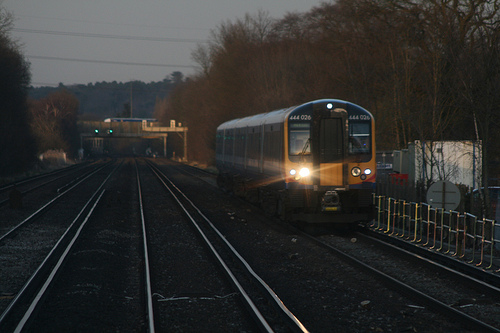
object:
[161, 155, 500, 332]
railroad tracks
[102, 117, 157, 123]
vehicle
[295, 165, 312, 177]
light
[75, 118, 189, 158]
bridge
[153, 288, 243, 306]
broken limbs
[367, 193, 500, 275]
fence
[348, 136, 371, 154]
windows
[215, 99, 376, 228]
train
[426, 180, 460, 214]
sign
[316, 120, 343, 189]
door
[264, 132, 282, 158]
window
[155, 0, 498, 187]
trees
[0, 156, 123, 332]
track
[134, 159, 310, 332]
track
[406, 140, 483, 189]
box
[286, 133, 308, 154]
window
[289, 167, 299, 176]
light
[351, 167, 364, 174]
light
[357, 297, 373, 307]
rocks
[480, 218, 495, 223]
railing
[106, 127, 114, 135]
light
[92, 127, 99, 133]
light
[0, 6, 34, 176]
tree